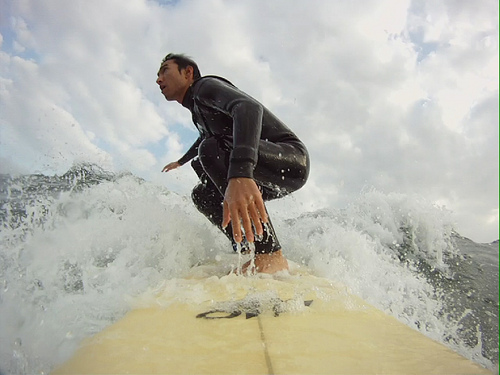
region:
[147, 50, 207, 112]
man on board looking left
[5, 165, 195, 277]
rumbling white ocean waves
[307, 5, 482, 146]
fluffy white clouds in sky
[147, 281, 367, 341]
surfboard with black lettering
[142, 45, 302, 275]
man with black wetsuit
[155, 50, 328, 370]
surfer on yellow board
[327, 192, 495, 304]
white and grey waves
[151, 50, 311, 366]
surfer crouching on board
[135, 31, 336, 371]
man surfing a giant wave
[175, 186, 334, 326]
barefeet on yellow surfboard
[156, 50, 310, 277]
a man riding a surfboard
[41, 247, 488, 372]
a surfboard under the man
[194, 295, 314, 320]
black writing on the surfboard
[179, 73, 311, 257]
black wet suit on the man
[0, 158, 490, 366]
violent waves around the man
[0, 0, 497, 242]
cloudy sky behind the man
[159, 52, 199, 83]
short, black hair on the man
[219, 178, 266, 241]
the man's left hand pointed toward the surfboard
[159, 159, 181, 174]
the man's right hand above the water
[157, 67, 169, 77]
man's eyes looking out at the sea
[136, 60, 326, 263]
surfer wearing black wetsuit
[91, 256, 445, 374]
white surfboard with black text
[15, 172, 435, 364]
white foam of wave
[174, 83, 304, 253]
full length black wetsuit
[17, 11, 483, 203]
clouds in the sky behind surfer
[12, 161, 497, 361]
wave surfer is riding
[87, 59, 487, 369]
surfer crouched on his surfboard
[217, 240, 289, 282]
feet of the surfboarder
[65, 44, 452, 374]
rider in black wetsuit on white surfboard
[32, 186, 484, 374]
swell of wave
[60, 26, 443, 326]
A man is riding a surfboard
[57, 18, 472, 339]
A man is in the water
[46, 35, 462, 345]
A person is in the ocean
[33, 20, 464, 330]
A man is in a surfing competition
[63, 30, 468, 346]
A man is riding an ocean wave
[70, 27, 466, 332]
The man is riding toward the shore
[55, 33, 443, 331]
The man is wearing a wetsuit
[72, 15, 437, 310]
The man has dark colored hair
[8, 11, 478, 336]
The man is under a cloudy sky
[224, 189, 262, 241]
The hand of a man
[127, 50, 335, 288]
person on surfboard in water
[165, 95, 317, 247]
black wetsuit on man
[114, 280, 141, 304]
water splashing on man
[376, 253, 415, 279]
water splashing on man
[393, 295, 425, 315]
water splashing on man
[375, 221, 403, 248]
water splashing on man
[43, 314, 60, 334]
water splashing on man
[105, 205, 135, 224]
water splashing on man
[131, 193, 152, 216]
water splashing on man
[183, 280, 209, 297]
water splashing on man